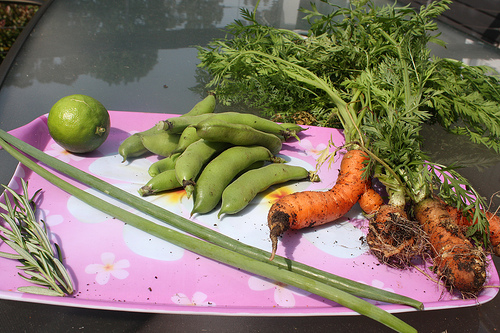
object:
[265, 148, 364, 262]
carrot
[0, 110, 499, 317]
plate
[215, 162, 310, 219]
beans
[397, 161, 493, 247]
leaves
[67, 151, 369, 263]
flower design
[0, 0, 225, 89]
shadow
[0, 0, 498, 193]
ground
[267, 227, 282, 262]
roots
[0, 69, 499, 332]
table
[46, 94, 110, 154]
lime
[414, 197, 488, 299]
vegetables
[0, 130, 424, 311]
vegetable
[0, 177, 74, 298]
herb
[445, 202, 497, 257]
vegetables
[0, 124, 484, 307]
surface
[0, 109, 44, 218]
side